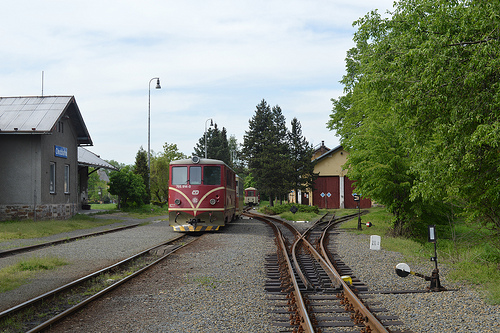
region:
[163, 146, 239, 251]
a red train with a plow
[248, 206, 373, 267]
spliting train tracks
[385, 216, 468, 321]
a black and white train track swithc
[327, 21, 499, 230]
green leafed trees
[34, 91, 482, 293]
a summer scene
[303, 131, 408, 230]
a tan and red train stall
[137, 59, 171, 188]
a hooked street lamp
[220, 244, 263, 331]
spread gravel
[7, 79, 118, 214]
a grey building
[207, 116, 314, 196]
a cluster of green pine trees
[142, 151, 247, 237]
the train on the tracks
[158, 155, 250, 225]
The train is red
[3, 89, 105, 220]
the building beside the tracks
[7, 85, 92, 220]
the building is gray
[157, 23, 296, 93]
the sky is cloudy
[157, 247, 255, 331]
the gravel is beside the tracks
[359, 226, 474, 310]
the junction box in the gravel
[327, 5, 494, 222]
The tree with green leaves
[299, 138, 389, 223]
The tan building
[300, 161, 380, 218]
the burgundy doors of the tan building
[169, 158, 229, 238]
red and yellow train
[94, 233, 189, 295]
gray train tracks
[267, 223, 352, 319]
gray train tracks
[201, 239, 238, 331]
gray gravel near train tracks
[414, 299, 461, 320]
gray gravel near train tracks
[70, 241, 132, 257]
gray gravel near train tracks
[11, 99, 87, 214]
gray building near train tracks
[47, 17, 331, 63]
white clouds against blue sky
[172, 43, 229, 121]
white clouds against blue sky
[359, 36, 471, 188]
trees with green leaves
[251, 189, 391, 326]
There are three tracks combined into one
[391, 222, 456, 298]
Black and white railroad signal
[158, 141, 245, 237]
Red and yellow train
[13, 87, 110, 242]
The building is grey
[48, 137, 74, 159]
Blue and white sign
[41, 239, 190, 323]
Grass in the tracks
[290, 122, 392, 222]
Building with large red doors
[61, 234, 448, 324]
The tracks are on gravel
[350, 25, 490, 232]
There are trees by the track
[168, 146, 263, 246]
There are two train cars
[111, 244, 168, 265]
A railroad track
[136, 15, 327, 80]
A white, cloudy sky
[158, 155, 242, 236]
A red train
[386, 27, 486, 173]
A green tree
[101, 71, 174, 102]
a lamp post high above the train tracks.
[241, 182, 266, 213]
A train car.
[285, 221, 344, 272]
Two train tracks twitch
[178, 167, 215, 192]
the train engineer's window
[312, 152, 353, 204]
A yellow and red building.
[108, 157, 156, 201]
Trees in the background.